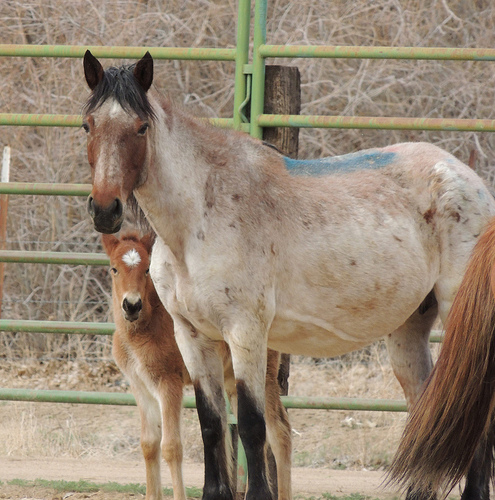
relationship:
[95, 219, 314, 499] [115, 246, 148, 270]
horse has spot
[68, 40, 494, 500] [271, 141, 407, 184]
horse has a mark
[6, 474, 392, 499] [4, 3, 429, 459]
grass in field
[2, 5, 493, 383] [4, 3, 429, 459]
grass in field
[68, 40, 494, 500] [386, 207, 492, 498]
horse has a tail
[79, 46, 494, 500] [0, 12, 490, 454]
horse in a pen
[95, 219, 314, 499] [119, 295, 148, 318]
horse has a nose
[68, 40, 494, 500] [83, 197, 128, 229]
horse has aa nose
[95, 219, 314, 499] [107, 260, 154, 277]
horse has eyes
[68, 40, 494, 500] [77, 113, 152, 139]
horse has eyes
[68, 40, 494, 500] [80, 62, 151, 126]
horse has hair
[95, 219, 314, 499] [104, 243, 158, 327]
horse has a face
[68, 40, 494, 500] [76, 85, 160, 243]
horse has a face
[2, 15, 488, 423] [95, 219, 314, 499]
fence behind horse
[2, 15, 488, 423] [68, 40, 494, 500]
fence behind horse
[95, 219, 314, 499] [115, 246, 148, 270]
horse has a spot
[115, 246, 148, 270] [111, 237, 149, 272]
spot on horse's forehead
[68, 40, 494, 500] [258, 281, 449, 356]
horse has a stomach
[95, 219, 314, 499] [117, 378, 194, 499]
horse has legs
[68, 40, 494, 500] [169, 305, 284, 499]
horse has legs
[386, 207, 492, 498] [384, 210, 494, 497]
tail of an animal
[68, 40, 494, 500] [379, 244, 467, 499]
horse has legs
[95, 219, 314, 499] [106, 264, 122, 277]
horse has an eye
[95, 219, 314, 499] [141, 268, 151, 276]
horse has an eye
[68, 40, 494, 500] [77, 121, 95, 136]
horse has an eye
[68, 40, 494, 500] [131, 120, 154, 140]
horse has an eye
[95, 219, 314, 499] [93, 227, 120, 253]
horse has an ear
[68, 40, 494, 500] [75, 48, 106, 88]
horse has an ear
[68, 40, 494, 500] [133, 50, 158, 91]
horse has an ear